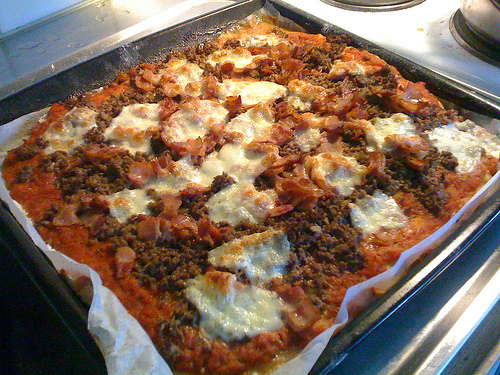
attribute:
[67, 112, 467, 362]
meat — grounded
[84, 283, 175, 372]
liner paper — white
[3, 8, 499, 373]
sauce — red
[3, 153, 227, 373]
sauce — red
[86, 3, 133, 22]
patch — additional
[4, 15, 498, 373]
food — burnt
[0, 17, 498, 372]
cheese — melted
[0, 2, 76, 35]
backdrop — blue